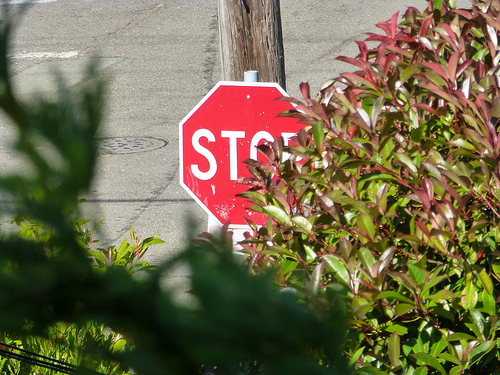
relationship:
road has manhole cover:
[2, 0, 476, 310] [98, 135, 169, 155]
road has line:
[2, 0, 476, 310] [9, 49, 77, 61]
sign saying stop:
[177, 80, 326, 228] [190, 127, 299, 181]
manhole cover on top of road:
[98, 135, 169, 155] [2, 0, 476, 310]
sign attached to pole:
[177, 80, 326, 228] [217, 2, 286, 88]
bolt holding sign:
[247, 94, 251, 99] [177, 80, 326, 228]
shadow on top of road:
[0, 198, 192, 203] [2, 0, 476, 310]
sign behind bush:
[177, 80, 326, 228] [193, 0, 499, 374]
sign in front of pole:
[177, 80, 326, 228] [217, 2, 286, 88]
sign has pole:
[177, 80, 326, 228] [244, 69, 259, 85]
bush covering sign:
[193, 0, 499, 374] [177, 80, 326, 228]